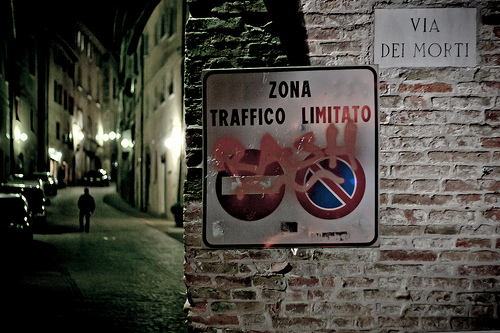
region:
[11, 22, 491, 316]
A street scene at night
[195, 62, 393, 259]
A traffic sign is on the wall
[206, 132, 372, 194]
Graffiti is painted on the sign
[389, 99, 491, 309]
The wall is made of bricks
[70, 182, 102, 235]
A person is walking up the street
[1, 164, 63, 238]
Automobiles are parked along the street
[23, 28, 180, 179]
Buildings are on both sides of the street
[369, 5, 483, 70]
A name plaque is part of the wall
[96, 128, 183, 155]
Lights are on the buildings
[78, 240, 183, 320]
The street is paved with bricks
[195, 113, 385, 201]
Painted grafitti on sign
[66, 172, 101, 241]
Man walking down dark roadway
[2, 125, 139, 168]
Streetlights along walls of the roadway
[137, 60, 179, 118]
windows above archway on the right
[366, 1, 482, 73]
Street sign in Italian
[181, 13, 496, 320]
old brick wall of building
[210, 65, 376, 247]
limited traffic zone sign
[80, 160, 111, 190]
car parked on left side of roadway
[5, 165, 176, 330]
curved cobblestone roadway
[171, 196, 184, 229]
black fire hydrant on sidewalk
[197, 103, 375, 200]
graffitti on traffic sign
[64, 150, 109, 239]
person walking alone down ally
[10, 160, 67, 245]
cars are parked on street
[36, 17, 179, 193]
residential buildings along a street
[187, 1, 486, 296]
signs on a brick wall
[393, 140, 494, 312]
brick and mortor wall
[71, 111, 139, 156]
building lights are on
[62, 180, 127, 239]
man walking on a paved road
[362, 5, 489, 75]
sign indicates street name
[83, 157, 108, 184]
car parked beside building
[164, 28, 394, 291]
a sign on a wall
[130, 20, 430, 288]
a sign on a brick wall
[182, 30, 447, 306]
a sign on a building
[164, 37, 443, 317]
a sign on a brick building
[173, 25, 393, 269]
a sign with graffiti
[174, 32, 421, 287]
a sign with red graffiti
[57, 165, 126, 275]
a person walking on the road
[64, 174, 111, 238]
a person walking at night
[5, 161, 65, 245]
vehcles parked on the road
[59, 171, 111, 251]
a man walking on road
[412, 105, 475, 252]
the walls are made of bricks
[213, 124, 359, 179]
there is graffiti on the sign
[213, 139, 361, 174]
the graffit is red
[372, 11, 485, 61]
the writing says via dei morti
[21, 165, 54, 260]
the cars are parked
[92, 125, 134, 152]
the lights are on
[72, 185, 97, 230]
the man is walking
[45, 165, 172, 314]
the corridor is narrow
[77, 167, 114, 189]
the car is black